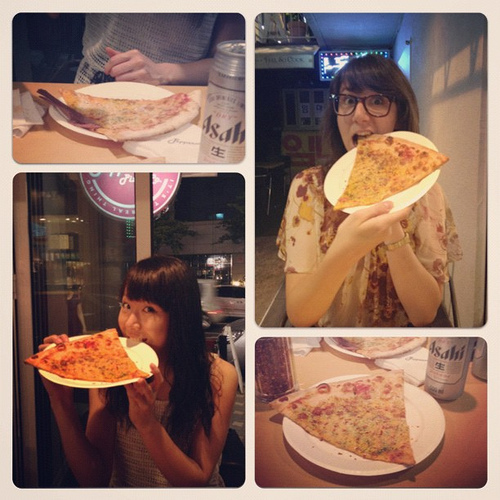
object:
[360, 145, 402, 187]
pizza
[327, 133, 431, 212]
plate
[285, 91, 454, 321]
woman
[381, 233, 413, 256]
watch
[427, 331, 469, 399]
can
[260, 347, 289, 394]
container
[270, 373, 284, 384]
peppers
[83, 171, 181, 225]
sign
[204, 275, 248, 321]
car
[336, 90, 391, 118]
glasses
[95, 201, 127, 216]
lettering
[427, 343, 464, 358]
asahi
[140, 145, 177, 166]
napkins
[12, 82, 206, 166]
table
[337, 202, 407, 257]
hand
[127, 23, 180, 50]
tank top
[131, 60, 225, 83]
arm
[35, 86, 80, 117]
knife